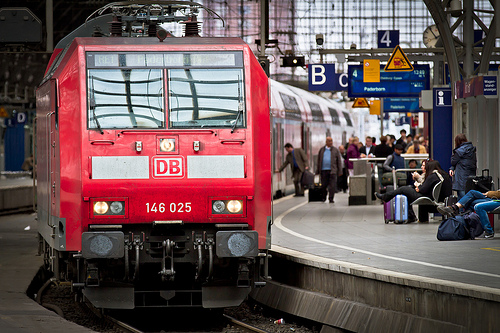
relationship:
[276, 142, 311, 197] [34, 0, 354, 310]
man leaning on train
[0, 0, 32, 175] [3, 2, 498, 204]
wall on building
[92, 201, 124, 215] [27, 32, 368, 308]
head light on train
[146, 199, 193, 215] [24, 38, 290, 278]
id numbers on train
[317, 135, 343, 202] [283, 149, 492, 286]
passenger standing on platform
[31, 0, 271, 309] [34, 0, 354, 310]
engine on train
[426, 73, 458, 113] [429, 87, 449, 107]
sign with letter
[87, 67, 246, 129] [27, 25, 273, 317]
windshield of train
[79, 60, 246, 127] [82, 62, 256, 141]
reflections in windshield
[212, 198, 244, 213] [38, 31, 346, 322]
headlight on train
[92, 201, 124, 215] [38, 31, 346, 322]
head light on train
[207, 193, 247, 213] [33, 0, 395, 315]
headlights on train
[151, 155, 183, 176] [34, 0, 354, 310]
logo on train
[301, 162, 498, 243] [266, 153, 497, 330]
luggage on platform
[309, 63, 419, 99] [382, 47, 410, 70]
letters on signs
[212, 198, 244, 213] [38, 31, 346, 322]
headlight of train